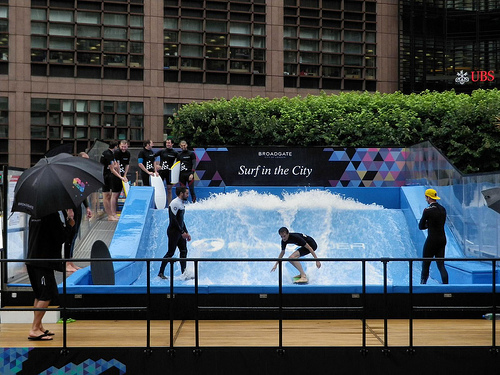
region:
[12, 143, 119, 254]
black umbrella with a colorful b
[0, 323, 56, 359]
black sandals on feet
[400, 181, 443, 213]
yellow and black hat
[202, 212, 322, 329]
man surfing on water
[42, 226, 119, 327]
black board in water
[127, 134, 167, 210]
person holding white surfboard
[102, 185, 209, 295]
man in black and white wet suit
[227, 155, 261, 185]
white letters that spell surf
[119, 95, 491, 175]
tall green trees by surf in city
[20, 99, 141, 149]
windows on a building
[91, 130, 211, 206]
A group of people in the background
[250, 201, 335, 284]
A person is surfing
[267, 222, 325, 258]
Person is wearing a black wetsuit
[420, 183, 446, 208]
Person is wearing a yellow cap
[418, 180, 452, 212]
Person's cap is on backwards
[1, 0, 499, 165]
A building in the background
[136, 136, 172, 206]
Man in the background is holding a surfboard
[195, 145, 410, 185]
A sign in the background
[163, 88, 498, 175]
A tree bush in the background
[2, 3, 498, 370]
Photo was taken outdoors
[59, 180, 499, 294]
Surf area set up.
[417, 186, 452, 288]
Man in a wetsuit and yellow hat.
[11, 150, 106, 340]
Man in a wetsuit holding an umbrella.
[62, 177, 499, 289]
Twho men in water, one surfing.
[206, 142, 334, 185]
Black sign with white lettering.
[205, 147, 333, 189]
Sign that says Surf in the City.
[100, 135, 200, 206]
People waiting for a turn to surf.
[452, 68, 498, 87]
UBS sign and logo.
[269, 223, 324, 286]
Man bending down to surf.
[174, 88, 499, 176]
Green bushes behind the surf area.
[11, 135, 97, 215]
the umbrella is black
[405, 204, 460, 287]
the wet suit is black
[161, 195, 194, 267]
the wet suit is black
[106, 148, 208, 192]
the wet suit is black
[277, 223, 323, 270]
the wet suit is black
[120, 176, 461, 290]
artificial wave pool for surfers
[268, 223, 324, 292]
man surfing in the wavepool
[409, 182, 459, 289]
man with a yellow hat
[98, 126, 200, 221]
people in line to surf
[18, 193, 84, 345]
person holding an umbrella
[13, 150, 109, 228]
black colored umbrella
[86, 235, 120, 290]
black surfboard on the edge of the pool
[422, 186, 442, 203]
yellow colored baseball cap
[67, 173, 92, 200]
colorful splotch on a black umbrella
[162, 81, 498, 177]
hedge behind a wave pool